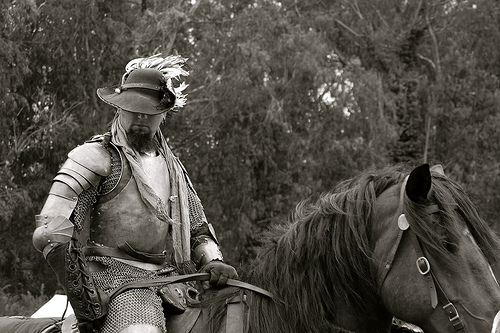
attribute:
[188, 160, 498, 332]
mane — white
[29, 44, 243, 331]
man — bearded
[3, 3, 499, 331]
photograph — black and white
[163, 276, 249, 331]
saddle — leather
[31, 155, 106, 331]
arm — bent